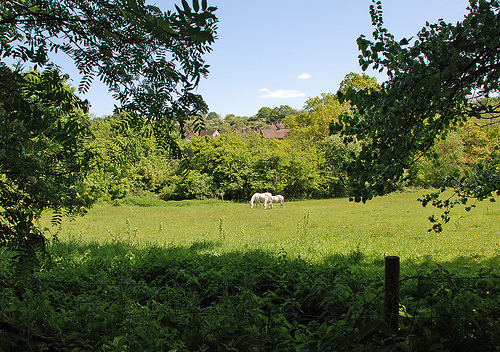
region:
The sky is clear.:
[0, 0, 499, 121]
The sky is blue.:
[1, 0, 495, 115]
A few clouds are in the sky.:
[0, 1, 497, 116]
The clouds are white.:
[256, 71, 319, 98]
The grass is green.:
[1, 188, 499, 350]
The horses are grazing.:
[246, 190, 286, 209]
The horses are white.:
[246, 189, 286, 209]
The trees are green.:
[0, 69, 499, 201]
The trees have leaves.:
[0, 68, 499, 202]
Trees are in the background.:
[0, 69, 499, 205]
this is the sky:
[229, 6, 326, 91]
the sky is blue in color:
[236, 7, 287, 69]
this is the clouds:
[262, 84, 299, 101]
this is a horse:
[259, 193, 291, 210]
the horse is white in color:
[271, 192, 281, 201]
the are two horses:
[249, 188, 284, 210]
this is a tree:
[356, 52, 493, 174]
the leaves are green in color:
[377, 80, 415, 135]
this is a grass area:
[187, 206, 349, 243]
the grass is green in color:
[255, 227, 311, 240]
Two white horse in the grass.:
[247, 188, 288, 212]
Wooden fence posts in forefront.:
[372, 251, 408, 339]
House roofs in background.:
[200, 121, 293, 142]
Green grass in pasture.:
[335, 198, 430, 240]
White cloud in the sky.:
[256, 76, 307, 101]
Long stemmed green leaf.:
[78, 72, 95, 99]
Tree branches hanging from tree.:
[324, 10, 489, 215]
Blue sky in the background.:
[237, 37, 277, 67]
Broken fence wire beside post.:
[360, 270, 436, 341]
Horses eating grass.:
[246, 193, 281, 213]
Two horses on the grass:
[247, 193, 284, 208]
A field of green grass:
[173, 213, 357, 238]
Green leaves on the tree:
[391, 88, 426, 139]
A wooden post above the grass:
[381, 254, 398, 324]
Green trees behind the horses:
[218, 145, 290, 168]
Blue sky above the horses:
[231, 30, 308, 66]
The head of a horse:
[249, 199, 254, 206]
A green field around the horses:
[57, 207, 499, 238]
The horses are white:
[254, 193, 295, 206]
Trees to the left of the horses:
[101, 143, 163, 193]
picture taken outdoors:
[17, 11, 486, 347]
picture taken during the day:
[20, 8, 492, 340]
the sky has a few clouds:
[20, 36, 412, 111]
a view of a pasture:
[26, 31, 495, 326]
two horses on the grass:
[240, 187, 290, 217]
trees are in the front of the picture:
[24, 103, 495, 218]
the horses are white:
[243, 186, 291, 211]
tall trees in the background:
[125, 108, 402, 137]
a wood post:
[379, 256, 413, 328]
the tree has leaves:
[343, 83, 439, 203]